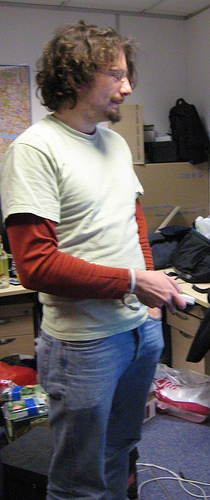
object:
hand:
[132, 263, 189, 321]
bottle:
[0, 231, 11, 292]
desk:
[0, 274, 41, 363]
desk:
[164, 272, 210, 381]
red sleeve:
[4, 207, 133, 306]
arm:
[0, 144, 135, 305]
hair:
[30, 16, 149, 118]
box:
[106, 98, 147, 169]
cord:
[134, 458, 210, 500]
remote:
[177, 292, 196, 306]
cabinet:
[0, 293, 37, 367]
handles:
[0, 333, 16, 347]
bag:
[0, 350, 40, 390]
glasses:
[110, 68, 121, 82]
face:
[97, 40, 133, 125]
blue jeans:
[34, 307, 165, 500]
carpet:
[0, 400, 210, 500]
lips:
[110, 98, 123, 111]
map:
[0, 58, 33, 177]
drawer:
[165, 304, 209, 341]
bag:
[162, 216, 210, 298]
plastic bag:
[150, 358, 210, 428]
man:
[0, 16, 188, 500]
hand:
[147, 303, 163, 322]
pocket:
[145, 313, 166, 360]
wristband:
[129, 267, 137, 297]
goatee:
[102, 94, 124, 125]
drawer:
[0, 309, 36, 340]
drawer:
[0, 329, 37, 362]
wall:
[0, 1, 210, 147]